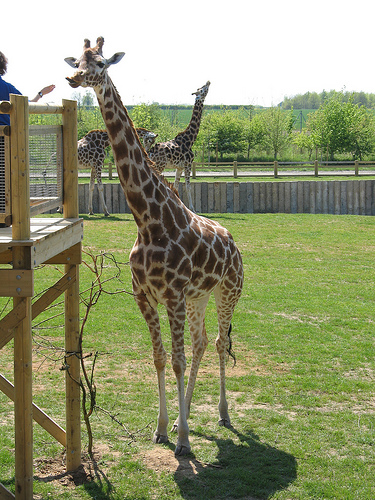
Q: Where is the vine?
A: On bridge.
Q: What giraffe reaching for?
A: Treat.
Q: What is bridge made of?
A: Logs.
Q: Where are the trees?
A: In background.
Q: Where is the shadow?
A: On ground.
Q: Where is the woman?
A: On platform.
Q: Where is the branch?
A: By platform.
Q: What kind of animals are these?
A: Giraffes.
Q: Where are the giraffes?
A: Zoo.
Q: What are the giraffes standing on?
A: Grass.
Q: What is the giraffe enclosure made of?
A: Wooden fence.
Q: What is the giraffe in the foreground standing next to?
A: Elevated deck.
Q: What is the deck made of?
A: Wood.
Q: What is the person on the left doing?
A: Feeding the giraffe.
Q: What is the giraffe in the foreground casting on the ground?
A: Shadow.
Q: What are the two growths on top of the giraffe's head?
A: Ossicones.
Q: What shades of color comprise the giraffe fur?
A: Brown and tan.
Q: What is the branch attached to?
A: A wood platform.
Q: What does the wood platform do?
A: Feed animals.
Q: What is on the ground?
A: Giraffe's shadow.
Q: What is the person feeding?
A: A giraffe.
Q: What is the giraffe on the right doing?
A: Looking up.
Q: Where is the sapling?
A: Left of giraffe.